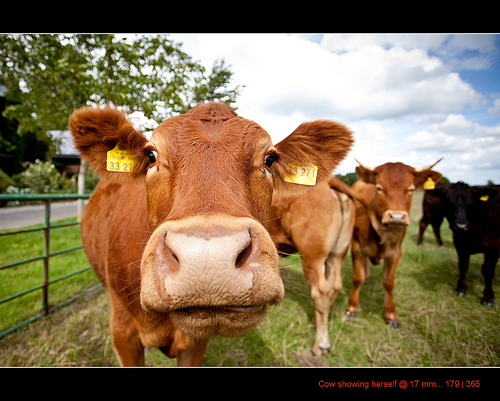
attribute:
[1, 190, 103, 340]
fence — green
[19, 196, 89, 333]
fence — green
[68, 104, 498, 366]
cows — brown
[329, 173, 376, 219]
tail — long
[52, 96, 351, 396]
cow — brown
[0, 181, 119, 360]
fence — green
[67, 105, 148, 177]
ear — tagged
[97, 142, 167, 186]
tag — yellow